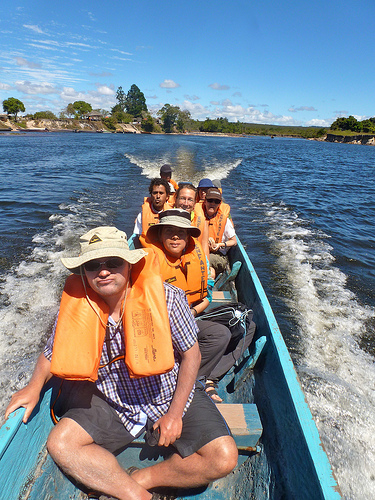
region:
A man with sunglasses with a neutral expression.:
[70, 248, 135, 294]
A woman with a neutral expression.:
[156, 225, 191, 256]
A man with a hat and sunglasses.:
[200, 190, 219, 212]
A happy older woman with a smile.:
[173, 183, 194, 213]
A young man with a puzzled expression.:
[148, 179, 169, 211]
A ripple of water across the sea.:
[282, 198, 373, 359]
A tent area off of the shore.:
[77, 105, 104, 125]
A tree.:
[3, 90, 34, 116]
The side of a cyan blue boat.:
[248, 316, 346, 499]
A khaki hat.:
[63, 229, 150, 263]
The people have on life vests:
[121, 153, 273, 427]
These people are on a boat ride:
[47, 183, 365, 444]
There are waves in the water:
[228, 197, 365, 439]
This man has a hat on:
[55, 227, 159, 315]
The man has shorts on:
[41, 405, 206, 496]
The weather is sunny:
[67, 25, 372, 150]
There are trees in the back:
[49, 95, 214, 153]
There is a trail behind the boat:
[108, 138, 262, 212]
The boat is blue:
[239, 353, 348, 484]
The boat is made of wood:
[251, 376, 304, 495]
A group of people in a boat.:
[5, 146, 343, 496]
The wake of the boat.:
[125, 135, 255, 187]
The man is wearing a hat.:
[48, 220, 145, 316]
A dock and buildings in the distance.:
[18, 106, 165, 141]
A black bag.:
[195, 295, 250, 347]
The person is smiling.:
[165, 167, 205, 221]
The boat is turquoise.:
[243, 371, 335, 494]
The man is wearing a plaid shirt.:
[31, 190, 211, 452]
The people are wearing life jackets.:
[34, 153, 259, 399]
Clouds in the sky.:
[7, 19, 310, 120]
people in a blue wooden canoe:
[24, 167, 349, 492]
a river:
[6, 130, 369, 468]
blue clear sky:
[2, 2, 374, 119]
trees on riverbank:
[4, 78, 192, 132]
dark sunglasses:
[78, 256, 126, 273]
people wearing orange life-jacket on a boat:
[67, 157, 232, 429]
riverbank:
[5, 103, 373, 143]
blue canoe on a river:
[13, 156, 331, 495]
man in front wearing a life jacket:
[48, 224, 224, 494]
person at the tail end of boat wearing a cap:
[157, 161, 175, 186]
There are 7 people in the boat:
[23, 146, 325, 495]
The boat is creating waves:
[6, 149, 356, 474]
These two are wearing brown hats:
[21, 211, 234, 290]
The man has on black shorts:
[43, 384, 295, 470]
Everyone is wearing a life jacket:
[21, 144, 321, 403]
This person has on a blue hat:
[199, 174, 218, 197]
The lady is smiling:
[173, 182, 202, 218]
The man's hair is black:
[136, 176, 176, 206]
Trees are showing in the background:
[2, 99, 361, 140]